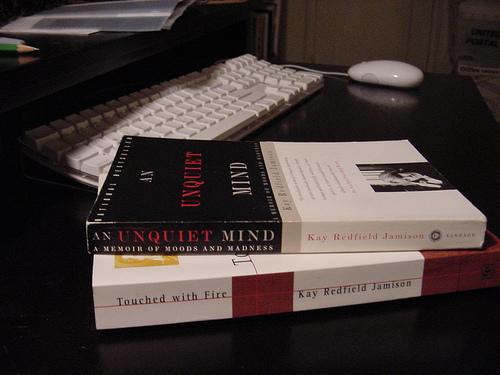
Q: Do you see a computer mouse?
A: Yes, there is a computer mouse.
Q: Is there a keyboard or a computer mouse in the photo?
A: Yes, there is a computer mouse.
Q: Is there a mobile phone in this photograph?
A: No, there are no cell phones.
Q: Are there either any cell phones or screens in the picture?
A: No, there are no cell phones or screens.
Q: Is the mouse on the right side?
A: Yes, the mouse is on the right of the image.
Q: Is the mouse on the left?
A: No, the mouse is on the right of the image.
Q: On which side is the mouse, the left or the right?
A: The mouse is on the right of the image.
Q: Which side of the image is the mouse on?
A: The mouse is on the right of the image.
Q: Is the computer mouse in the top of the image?
A: Yes, the computer mouse is in the top of the image.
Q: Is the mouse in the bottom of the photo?
A: No, the mouse is in the top of the image.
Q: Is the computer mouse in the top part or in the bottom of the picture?
A: The computer mouse is in the top of the image.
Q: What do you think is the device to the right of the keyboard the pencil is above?
A: The device is a computer mouse.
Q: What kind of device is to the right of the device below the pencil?
A: The device is a computer mouse.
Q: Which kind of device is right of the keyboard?
A: The device is a computer mouse.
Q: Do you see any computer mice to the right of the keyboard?
A: Yes, there is a computer mouse to the right of the keyboard.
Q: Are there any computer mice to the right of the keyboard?
A: Yes, there is a computer mouse to the right of the keyboard.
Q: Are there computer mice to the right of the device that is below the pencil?
A: Yes, there is a computer mouse to the right of the keyboard.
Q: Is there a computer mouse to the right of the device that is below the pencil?
A: Yes, there is a computer mouse to the right of the keyboard.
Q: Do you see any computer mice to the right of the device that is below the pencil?
A: Yes, there is a computer mouse to the right of the keyboard.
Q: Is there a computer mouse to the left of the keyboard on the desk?
A: No, the computer mouse is to the right of the keyboard.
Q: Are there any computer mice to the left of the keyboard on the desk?
A: No, the computer mouse is to the right of the keyboard.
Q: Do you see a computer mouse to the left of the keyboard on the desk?
A: No, the computer mouse is to the right of the keyboard.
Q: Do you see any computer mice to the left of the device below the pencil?
A: No, the computer mouse is to the right of the keyboard.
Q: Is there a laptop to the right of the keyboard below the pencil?
A: No, there is a computer mouse to the right of the keyboard.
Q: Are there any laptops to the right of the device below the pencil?
A: No, there is a computer mouse to the right of the keyboard.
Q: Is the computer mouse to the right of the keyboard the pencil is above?
A: Yes, the computer mouse is to the right of the keyboard.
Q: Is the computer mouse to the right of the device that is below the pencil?
A: Yes, the computer mouse is to the right of the keyboard.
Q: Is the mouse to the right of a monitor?
A: No, the mouse is to the right of the keyboard.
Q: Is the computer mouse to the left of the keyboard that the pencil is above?
A: No, the computer mouse is to the right of the keyboard.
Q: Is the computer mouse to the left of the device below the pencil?
A: No, the computer mouse is to the right of the keyboard.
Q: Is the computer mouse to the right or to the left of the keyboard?
A: The computer mouse is to the right of the keyboard.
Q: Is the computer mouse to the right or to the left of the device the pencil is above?
A: The computer mouse is to the right of the keyboard.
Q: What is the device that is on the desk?
A: The device is a computer mouse.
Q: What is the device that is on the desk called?
A: The device is a computer mouse.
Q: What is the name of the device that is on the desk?
A: The device is a computer mouse.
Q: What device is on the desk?
A: The device is a computer mouse.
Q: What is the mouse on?
A: The mouse is on the desk.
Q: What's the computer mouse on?
A: The mouse is on the desk.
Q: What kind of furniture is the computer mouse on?
A: The computer mouse is on the desk.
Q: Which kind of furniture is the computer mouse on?
A: The computer mouse is on the desk.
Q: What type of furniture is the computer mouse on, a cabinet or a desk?
A: The computer mouse is on a desk.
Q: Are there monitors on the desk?
A: No, there is a computer mouse on the desk.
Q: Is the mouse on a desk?
A: Yes, the mouse is on a desk.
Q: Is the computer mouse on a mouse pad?
A: No, the computer mouse is on a desk.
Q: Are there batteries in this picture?
A: No, there are no batteries.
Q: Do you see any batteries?
A: No, there are no batteries.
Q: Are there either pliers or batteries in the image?
A: No, there are no batteries or pliers.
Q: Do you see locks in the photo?
A: No, there are no locks.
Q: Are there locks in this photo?
A: No, there are no locks.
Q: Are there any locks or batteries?
A: No, there are no locks or batteries.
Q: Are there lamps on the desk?
A: No, there is a book on the desk.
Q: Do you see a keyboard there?
A: Yes, there is a keyboard.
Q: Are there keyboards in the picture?
A: Yes, there is a keyboard.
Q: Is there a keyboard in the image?
A: Yes, there is a keyboard.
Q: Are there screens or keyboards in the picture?
A: Yes, there is a keyboard.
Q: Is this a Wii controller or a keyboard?
A: This is a keyboard.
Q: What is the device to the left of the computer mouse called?
A: The device is a keyboard.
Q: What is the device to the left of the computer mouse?
A: The device is a keyboard.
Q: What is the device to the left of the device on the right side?
A: The device is a keyboard.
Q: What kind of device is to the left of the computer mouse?
A: The device is a keyboard.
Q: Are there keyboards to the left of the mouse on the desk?
A: Yes, there is a keyboard to the left of the computer mouse.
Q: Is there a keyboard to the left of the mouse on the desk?
A: Yes, there is a keyboard to the left of the computer mouse.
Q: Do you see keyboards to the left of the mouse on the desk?
A: Yes, there is a keyboard to the left of the computer mouse.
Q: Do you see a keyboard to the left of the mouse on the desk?
A: Yes, there is a keyboard to the left of the computer mouse.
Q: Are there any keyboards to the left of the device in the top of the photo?
A: Yes, there is a keyboard to the left of the computer mouse.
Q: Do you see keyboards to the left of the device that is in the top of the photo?
A: Yes, there is a keyboard to the left of the computer mouse.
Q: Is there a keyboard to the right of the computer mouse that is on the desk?
A: No, the keyboard is to the left of the mouse.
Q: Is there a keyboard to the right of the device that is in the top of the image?
A: No, the keyboard is to the left of the mouse.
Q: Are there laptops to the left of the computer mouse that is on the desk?
A: No, there is a keyboard to the left of the mouse.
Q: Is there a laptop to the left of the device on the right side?
A: No, there is a keyboard to the left of the mouse.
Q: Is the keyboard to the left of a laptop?
A: No, the keyboard is to the left of the computer mouse.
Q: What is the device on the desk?
A: The device is a keyboard.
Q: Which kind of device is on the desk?
A: The device is a keyboard.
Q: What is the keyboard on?
A: The keyboard is on the desk.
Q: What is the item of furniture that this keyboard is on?
A: The piece of furniture is a desk.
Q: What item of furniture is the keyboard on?
A: The keyboard is on the desk.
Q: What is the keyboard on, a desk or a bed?
A: The keyboard is on a desk.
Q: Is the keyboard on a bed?
A: No, the keyboard is on the desk.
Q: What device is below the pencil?
A: The device is a keyboard.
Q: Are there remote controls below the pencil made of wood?
A: No, there is a keyboard below the pencil.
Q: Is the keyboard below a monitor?
A: No, the keyboard is below the pencil.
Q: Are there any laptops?
A: No, there are no laptops.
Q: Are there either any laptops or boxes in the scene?
A: No, there are no laptops or boxes.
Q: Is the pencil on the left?
A: Yes, the pencil is on the left of the image.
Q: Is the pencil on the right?
A: No, the pencil is on the left of the image.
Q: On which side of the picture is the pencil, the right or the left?
A: The pencil is on the left of the image.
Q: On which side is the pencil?
A: The pencil is on the left of the image.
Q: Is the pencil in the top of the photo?
A: Yes, the pencil is in the top of the image.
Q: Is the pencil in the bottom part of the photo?
A: No, the pencil is in the top of the image.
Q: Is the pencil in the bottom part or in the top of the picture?
A: The pencil is in the top of the image.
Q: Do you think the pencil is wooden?
A: Yes, the pencil is wooden.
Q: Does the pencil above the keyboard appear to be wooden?
A: Yes, the pencil is wooden.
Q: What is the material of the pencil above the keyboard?
A: The pencil is made of wood.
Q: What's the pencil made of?
A: The pencil is made of wood.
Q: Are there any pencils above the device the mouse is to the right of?
A: Yes, there is a pencil above the keyboard.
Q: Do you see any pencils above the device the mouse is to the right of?
A: Yes, there is a pencil above the keyboard.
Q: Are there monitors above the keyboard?
A: No, there is a pencil above the keyboard.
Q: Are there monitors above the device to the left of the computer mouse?
A: No, there is a pencil above the keyboard.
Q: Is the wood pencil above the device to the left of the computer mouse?
A: Yes, the pencil is above the keyboard.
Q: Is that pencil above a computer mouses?
A: No, the pencil is above the keyboard.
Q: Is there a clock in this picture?
A: No, there are no clocks.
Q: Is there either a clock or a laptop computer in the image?
A: No, there are no clocks or laptops.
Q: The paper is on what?
A: The paper is on the desk.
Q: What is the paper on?
A: The paper is on the desk.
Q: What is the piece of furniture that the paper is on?
A: The piece of furniture is a desk.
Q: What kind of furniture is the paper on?
A: The paper is on the desk.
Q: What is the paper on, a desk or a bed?
A: The paper is on a desk.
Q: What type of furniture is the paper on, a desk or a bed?
A: The paper is on a desk.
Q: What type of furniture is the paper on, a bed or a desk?
A: The paper is on a desk.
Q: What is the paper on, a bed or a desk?
A: The paper is on a desk.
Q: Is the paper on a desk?
A: Yes, the paper is on a desk.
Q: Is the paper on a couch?
A: No, the paper is on a desk.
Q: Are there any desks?
A: Yes, there is a desk.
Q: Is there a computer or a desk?
A: Yes, there is a desk.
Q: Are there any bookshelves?
A: No, there are no bookshelves.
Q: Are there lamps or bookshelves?
A: No, there are no bookshelves or lamps.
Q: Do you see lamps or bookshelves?
A: No, there are no bookshelves or lamps.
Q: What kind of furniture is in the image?
A: The furniture is a desk.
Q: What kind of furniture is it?
A: The piece of furniture is a desk.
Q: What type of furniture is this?
A: That is a desk.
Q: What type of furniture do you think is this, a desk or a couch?
A: That is a desk.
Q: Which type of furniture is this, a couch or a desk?
A: That is a desk.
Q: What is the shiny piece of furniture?
A: The piece of furniture is a desk.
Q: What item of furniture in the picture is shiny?
A: The piece of furniture is a desk.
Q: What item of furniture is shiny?
A: The piece of furniture is a desk.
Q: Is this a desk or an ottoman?
A: This is a desk.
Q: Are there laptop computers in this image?
A: No, there are no laptop computers.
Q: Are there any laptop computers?
A: No, there are no laptop computers.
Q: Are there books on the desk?
A: Yes, there is a book on the desk.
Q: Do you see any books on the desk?
A: Yes, there is a book on the desk.